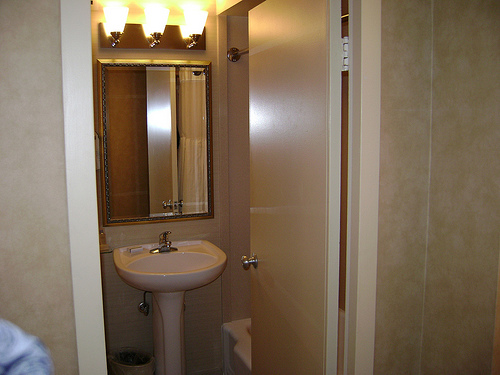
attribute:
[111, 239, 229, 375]
sink — porcelain, white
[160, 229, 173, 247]
faucet — metallic, silver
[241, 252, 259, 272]
door knob — metal, silver, chrome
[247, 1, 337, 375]
door — white, open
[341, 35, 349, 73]
hinge — white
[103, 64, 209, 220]
mirror — hanging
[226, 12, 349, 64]
shower rod — metal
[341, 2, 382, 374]
frame — wooden, white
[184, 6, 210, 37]
light — illuminated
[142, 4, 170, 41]
light — illuminated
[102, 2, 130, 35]
light — illuminated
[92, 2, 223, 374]
wall — brown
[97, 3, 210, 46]
lights — on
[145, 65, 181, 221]
door — reflected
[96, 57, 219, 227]
frame — gold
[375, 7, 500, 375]
wallpaper — beige, white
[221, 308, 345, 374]
bathtub — white